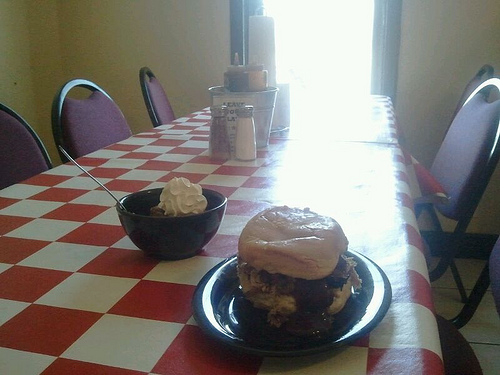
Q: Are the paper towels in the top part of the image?
A: Yes, the paper towels are in the top of the image.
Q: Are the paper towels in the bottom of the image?
A: No, the paper towels are in the top of the image.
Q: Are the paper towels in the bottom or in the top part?
A: The paper towels are in the top of the image.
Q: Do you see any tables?
A: Yes, there is a table.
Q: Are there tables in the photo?
A: Yes, there is a table.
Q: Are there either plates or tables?
A: Yes, there is a table.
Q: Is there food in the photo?
A: Yes, there is food.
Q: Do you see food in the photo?
A: Yes, there is food.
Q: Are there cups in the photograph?
A: No, there are no cups.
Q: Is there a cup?
A: No, there are no cups.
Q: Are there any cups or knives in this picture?
A: No, there are no cups or knives.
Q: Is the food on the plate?
A: Yes, the food is on the plate.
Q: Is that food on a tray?
A: No, the food is on the plate.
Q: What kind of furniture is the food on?
A: The food is on the table.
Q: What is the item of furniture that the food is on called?
A: The piece of furniture is a table.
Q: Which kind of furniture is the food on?
A: The food is on the table.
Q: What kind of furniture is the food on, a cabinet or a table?
A: The food is on a table.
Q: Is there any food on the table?
A: Yes, there is food on the table.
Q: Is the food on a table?
A: Yes, the food is on a table.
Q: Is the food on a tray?
A: No, the food is on a table.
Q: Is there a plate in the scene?
A: Yes, there is a plate.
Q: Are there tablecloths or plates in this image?
A: Yes, there is a plate.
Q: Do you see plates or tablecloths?
A: Yes, there is a plate.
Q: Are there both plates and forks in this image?
A: No, there is a plate but no forks.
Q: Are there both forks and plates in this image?
A: No, there is a plate but no forks.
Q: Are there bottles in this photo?
A: No, there are no bottles.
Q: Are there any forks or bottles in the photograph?
A: No, there are no bottles or forks.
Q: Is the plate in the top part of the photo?
A: No, the plate is in the bottom of the image.